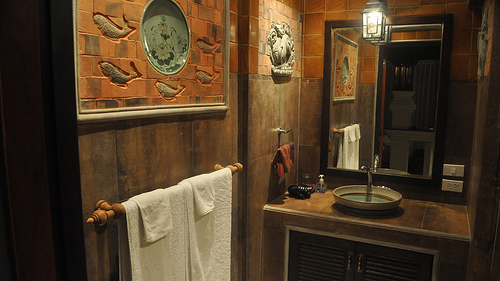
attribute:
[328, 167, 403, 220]
sink — bowl design, bowl shaped, bowl, modern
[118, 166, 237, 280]
towels — white, large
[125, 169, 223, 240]
washcloths — white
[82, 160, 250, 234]
towel rack — brown, wooden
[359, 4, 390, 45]
light fixture — modern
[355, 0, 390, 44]
cover — black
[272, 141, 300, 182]
washcloth — red, colorful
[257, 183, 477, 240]
countertop — marble, brown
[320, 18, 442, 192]
mirror — framed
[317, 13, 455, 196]
frame — black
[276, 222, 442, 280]
cabinet — black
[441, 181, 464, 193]
electrical outlets — white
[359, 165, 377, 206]
faucet — modern